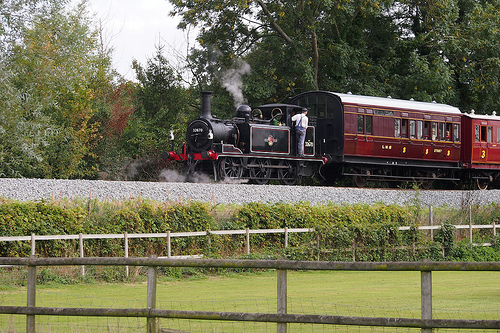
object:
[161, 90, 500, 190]
train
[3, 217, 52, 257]
ground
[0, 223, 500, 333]
fence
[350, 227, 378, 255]
ground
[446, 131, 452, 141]
person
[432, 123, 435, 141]
person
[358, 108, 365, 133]
window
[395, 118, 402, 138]
window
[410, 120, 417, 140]
window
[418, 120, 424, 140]
window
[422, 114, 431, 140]
window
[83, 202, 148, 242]
shrub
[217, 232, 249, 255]
patch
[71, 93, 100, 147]
yellow leaves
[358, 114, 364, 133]
windows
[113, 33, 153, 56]
sky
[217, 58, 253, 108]
steam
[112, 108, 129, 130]
leaves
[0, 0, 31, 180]
tree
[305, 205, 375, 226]
plants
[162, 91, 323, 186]
engine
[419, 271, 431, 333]
wooden post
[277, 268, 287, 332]
wooden post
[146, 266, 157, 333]
wooden post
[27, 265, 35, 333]
wooden post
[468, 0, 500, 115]
trees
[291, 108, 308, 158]
engineer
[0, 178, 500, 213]
rocks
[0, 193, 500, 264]
weeds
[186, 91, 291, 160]
steam engine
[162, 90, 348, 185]
front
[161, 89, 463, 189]
passenger car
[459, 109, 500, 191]
passenger car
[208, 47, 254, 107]
smoke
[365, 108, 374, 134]
windows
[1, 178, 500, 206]
gravel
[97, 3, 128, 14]
sky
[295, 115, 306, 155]
overalls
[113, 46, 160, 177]
tree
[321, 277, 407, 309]
land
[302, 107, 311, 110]
hat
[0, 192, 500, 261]
foliage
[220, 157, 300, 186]
wheels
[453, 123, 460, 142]
window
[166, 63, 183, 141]
trees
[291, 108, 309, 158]
conductor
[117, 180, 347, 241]
bank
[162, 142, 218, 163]
guard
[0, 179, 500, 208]
bed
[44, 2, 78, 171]
tree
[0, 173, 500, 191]
track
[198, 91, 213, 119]
stack